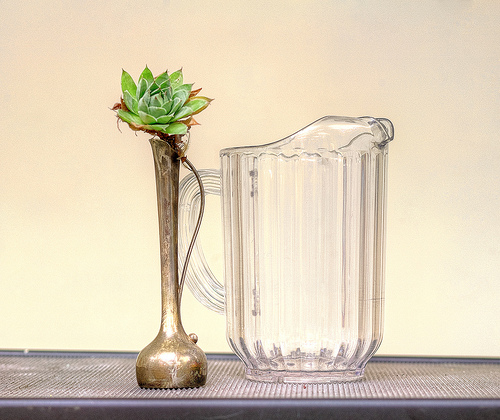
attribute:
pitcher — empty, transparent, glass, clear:
[207, 117, 396, 382]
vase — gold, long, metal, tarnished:
[136, 134, 206, 390]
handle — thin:
[180, 141, 204, 301]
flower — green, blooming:
[110, 64, 215, 154]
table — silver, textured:
[0, 350, 499, 419]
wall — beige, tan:
[2, 1, 499, 357]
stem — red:
[160, 133, 180, 148]